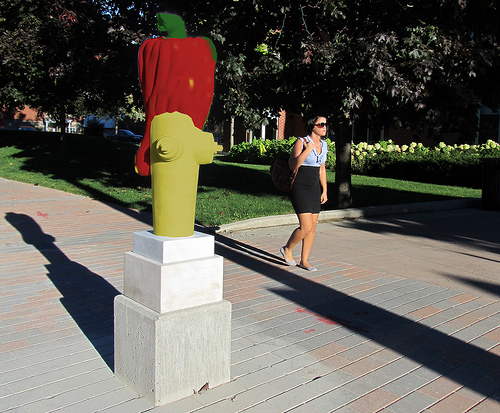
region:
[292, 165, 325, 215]
a tight black squirt on a woman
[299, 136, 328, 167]
a light blue top on a woman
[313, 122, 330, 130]
sunglasses on a woman's face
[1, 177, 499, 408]
a brick walkway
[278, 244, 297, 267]
a light blue shoe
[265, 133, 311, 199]
a brown bag carried on a woman's shoulder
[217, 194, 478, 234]
a curb behind a woman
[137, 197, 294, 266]
the shadow of a woma on the ground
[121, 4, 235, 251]
a chili pepper fire hydrant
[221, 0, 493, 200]
a tree behind a woman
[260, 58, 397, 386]
woman walking on pathway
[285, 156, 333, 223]
woman wearing black skirt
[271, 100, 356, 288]
this is a woman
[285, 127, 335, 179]
woman wearing blue shirt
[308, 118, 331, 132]
woman wearing dark glasses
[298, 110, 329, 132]
woman with dark hair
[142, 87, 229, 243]
green statue on pedestal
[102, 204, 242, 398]
square light statue pedestal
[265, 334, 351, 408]
light grey brick walkway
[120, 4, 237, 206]
red and green statue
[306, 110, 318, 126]
Person has dark hair.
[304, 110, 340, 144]
Person has short hair.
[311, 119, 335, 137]
Sunglasses on person's face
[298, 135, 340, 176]
Person wearing gray shirt.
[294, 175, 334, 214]
Person wearing black skirt.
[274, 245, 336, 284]
Person wearing gray flats.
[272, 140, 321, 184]
Person carrying brown bag on shoulder.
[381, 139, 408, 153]
White flowers on plants.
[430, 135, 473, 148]
White flowers on pants.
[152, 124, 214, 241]
Yellow fire hydrant on concrete blocks.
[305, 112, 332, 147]
woman is wearing sunglasses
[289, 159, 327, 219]
woman wearing a skirt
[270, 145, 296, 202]
woman carrying a purse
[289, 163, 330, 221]
woman's skirt is black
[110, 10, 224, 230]
red and yellow statue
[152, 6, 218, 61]
green piece on top of statue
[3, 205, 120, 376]
shadow of statue on ground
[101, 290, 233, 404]
base of statue made of concrete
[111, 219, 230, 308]
part of statue is white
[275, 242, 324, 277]
woman is wearing flats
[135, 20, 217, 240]
The statue is yellow and red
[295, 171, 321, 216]
her skirt is black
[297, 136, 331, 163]
her shirt is blue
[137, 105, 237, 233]
the bottom is yellow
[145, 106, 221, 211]
the hydrant is yellow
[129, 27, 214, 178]
The strawberry is red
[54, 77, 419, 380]
Statue in a park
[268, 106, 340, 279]
Woman next to the statue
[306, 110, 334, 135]
she is wearing sunglasses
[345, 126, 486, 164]
wall of yellow flowers